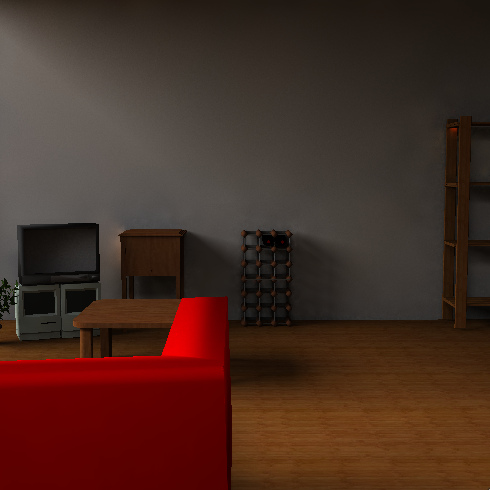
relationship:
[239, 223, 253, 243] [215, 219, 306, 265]
wooden ball on shelf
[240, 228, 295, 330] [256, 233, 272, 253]
wine rack holding wine bottle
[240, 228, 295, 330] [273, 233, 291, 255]
wine rack holding wine bottle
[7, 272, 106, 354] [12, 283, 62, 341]
stand made of monitors monitor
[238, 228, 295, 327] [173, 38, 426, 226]
wine rack standing against wall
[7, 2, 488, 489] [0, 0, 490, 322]
living room with wall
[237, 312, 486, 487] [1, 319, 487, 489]
tile on floor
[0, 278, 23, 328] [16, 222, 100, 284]
plant next to television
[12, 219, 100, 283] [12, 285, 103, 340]
television on stand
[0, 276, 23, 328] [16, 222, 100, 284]
plant by television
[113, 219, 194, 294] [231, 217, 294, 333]
table by wine rack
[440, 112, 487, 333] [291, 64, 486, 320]
wooden shelf against wall